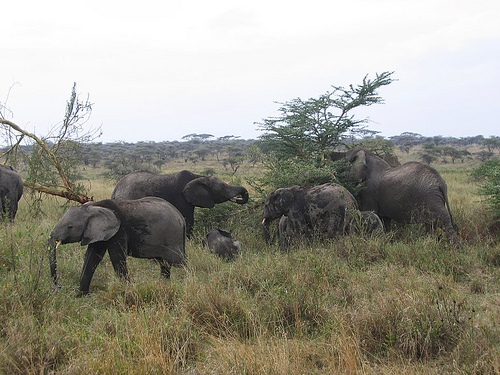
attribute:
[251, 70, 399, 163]
tree — thorny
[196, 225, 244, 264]
elephant — baby 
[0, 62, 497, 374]
vegetation — long 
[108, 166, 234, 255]
elephant — gray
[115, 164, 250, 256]
elephant — gray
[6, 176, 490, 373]
plain — grassy 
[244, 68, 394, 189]
tree — large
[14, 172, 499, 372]
grass — tall 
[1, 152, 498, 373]
grass — long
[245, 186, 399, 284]
elephant — gray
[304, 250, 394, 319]
grass — tall 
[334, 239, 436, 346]
grass — tall 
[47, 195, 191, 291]
elephant — gray